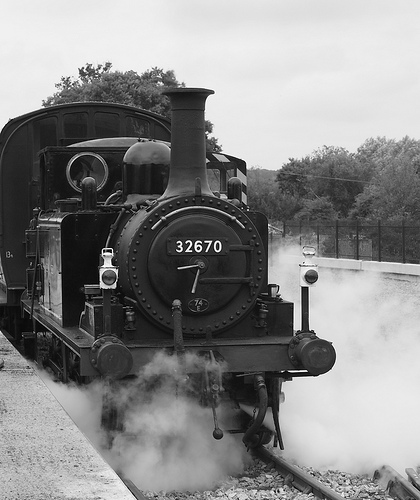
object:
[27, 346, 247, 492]
steam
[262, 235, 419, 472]
steam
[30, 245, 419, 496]
smoke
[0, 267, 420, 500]
ground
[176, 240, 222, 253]
number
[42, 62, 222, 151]
tree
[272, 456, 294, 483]
steel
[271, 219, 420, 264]
fence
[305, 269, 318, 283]
headlight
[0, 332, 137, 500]
platform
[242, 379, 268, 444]
pipe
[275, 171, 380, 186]
wire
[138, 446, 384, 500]
pebbles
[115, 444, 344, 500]
rail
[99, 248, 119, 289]
light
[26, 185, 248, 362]
metal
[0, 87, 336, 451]
black train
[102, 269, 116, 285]
headlight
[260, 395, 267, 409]
part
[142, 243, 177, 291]
part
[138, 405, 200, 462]
part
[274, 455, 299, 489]
part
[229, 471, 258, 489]
part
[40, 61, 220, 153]
leaves